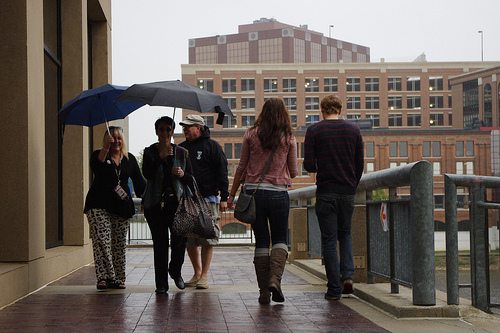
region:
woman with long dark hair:
[231, 94, 301, 311]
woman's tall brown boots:
[240, 236, 300, 311]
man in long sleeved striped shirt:
[300, 91, 373, 306]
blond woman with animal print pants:
[91, 121, 138, 297]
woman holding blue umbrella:
[41, 76, 141, 296]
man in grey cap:
[176, 109, 214, 151]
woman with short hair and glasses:
[145, 111, 197, 295]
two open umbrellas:
[48, 76, 233, 143]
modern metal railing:
[352, 152, 439, 309]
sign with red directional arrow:
[368, 200, 396, 235]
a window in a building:
[193, 76, 214, 98]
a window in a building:
[220, 75, 235, 91]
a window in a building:
[239, 75, 256, 97]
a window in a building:
[260, 72, 279, 94]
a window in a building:
[282, 74, 301, 93]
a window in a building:
[306, 75, 319, 90]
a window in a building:
[321, 73, 337, 90]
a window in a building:
[346, 75, 361, 92]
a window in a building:
[363, 73, 377, 91]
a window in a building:
[387, 74, 401, 89]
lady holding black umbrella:
[121, 60, 249, 145]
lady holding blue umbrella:
[48, 72, 165, 171]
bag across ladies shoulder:
[219, 87, 309, 318]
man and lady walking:
[225, 80, 388, 322]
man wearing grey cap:
[170, 110, 239, 316]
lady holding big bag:
[165, 155, 220, 251]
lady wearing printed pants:
[75, 173, 160, 321]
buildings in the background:
[178, 32, 498, 197]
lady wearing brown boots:
[235, 216, 307, 331]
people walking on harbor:
[16, 74, 396, 308]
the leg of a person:
[268, 208, 294, 321]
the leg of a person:
[244, 209, 276, 309]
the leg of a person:
[313, 195, 343, 303]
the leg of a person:
[336, 195, 363, 305]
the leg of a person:
[196, 211, 223, 296]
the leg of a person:
[179, 221, 204, 285]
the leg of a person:
[169, 220, 186, 290]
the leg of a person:
[148, 224, 170, 301]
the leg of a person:
[111, 215, 133, 287]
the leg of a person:
[83, 202, 113, 291]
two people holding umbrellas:
[65, 71, 223, 308]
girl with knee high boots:
[248, 100, 305, 308]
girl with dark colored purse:
[222, 55, 304, 306]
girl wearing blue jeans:
[244, 150, 312, 311]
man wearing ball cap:
[155, 100, 230, 188]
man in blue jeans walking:
[280, 91, 381, 328]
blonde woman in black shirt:
[80, 112, 145, 317]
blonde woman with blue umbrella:
[64, 78, 186, 329]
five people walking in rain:
[75, 85, 380, 330]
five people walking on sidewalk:
[60, 65, 420, 306]